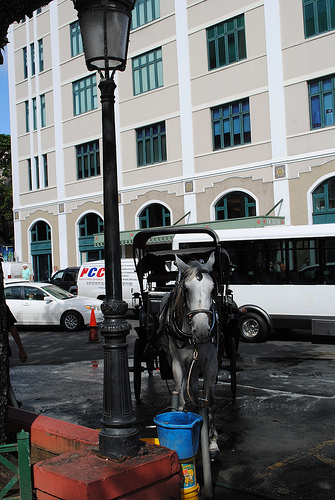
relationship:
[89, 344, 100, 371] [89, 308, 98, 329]
reflection of cone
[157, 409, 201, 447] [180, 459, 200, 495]
blue bucket sitting on top of bucket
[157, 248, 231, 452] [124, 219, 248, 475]
horse pulling carriage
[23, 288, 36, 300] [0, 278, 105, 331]
person in car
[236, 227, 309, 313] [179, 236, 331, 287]
white bus has windows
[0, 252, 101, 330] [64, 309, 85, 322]
car has tire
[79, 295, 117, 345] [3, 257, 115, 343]
cone by car